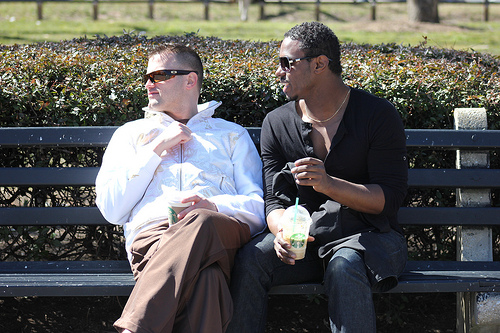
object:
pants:
[232, 226, 406, 332]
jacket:
[95, 101, 266, 264]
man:
[95, 46, 267, 332]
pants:
[109, 209, 254, 332]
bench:
[1, 124, 499, 330]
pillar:
[453, 106, 497, 332]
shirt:
[262, 90, 410, 235]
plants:
[1, 32, 499, 125]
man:
[232, 23, 412, 332]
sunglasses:
[277, 54, 317, 74]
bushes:
[0, 0, 500, 333]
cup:
[283, 203, 311, 259]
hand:
[279, 222, 310, 262]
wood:
[398, 263, 500, 295]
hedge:
[0, 35, 86, 127]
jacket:
[255, 84, 413, 286]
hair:
[148, 44, 204, 90]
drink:
[167, 198, 195, 227]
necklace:
[302, 89, 349, 123]